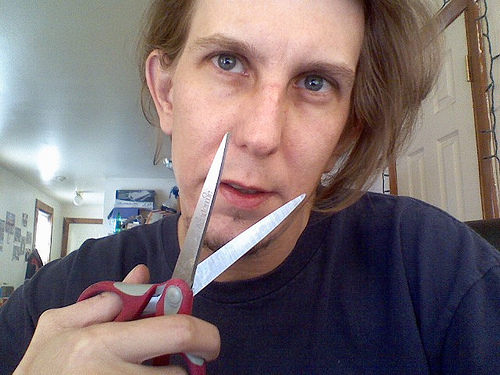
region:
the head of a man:
[171, 13, 403, 200]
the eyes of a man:
[190, 30, 298, 122]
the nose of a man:
[229, 91, 297, 167]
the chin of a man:
[177, 190, 282, 284]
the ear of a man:
[120, 25, 216, 161]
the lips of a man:
[188, 165, 304, 230]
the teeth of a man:
[164, 151, 322, 269]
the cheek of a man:
[150, 87, 248, 241]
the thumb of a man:
[40, 252, 170, 344]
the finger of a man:
[94, 310, 254, 357]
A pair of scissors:
[68, 133, 289, 363]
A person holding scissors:
[6, 8, 493, 368]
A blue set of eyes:
[206, 43, 341, 114]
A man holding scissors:
[2, 2, 499, 368]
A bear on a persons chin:
[177, 207, 285, 264]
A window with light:
[25, 200, 60, 272]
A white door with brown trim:
[381, 9, 493, 224]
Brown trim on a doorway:
[462, 6, 494, 226]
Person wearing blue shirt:
[1, 0, 496, 374]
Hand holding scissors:
[31, 128, 292, 372]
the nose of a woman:
[216, 105, 294, 188]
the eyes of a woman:
[170, 38, 356, 118]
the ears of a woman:
[133, 36, 201, 143]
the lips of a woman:
[187, 156, 304, 227]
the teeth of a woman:
[193, 156, 308, 226]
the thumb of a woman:
[66, 247, 174, 339]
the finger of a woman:
[81, 287, 265, 355]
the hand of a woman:
[48, 267, 245, 364]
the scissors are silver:
[212, 246, 239, 266]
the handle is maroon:
[124, 296, 136, 313]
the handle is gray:
[123, 282, 140, 294]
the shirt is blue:
[328, 302, 378, 335]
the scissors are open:
[191, 200, 259, 259]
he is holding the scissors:
[93, 283, 190, 350]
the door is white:
[434, 124, 466, 174]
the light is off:
[70, 193, 87, 206]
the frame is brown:
[475, 110, 490, 140]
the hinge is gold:
[459, 53, 472, 85]